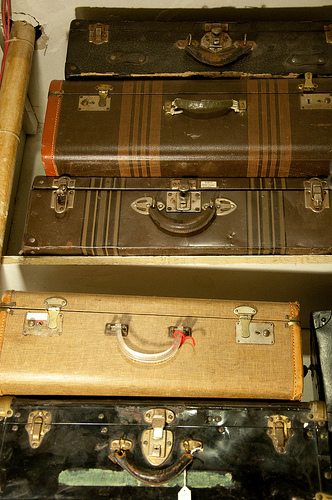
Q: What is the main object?
A: Suitcase.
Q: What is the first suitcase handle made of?
A: Plastic.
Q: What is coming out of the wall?
A: Pipe.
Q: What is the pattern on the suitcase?
A: Stripe.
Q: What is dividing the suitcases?
A: Wall.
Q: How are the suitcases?
A: In a group.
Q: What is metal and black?
A: The suitcase.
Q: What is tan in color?
A: The suitcase.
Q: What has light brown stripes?
A: A brown suitcase.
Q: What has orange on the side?
A: A brown suitcase.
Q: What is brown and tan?
A: A luggage is.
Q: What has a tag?
A: A metal suitcase.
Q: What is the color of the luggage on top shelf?
A: Brown.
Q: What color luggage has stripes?
A: Brown.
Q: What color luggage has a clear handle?
A: Beige.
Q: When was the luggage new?
A: A long time ago.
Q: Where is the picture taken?
A: In a shop.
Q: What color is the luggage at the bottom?
A: Black.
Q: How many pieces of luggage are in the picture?
A: Five.